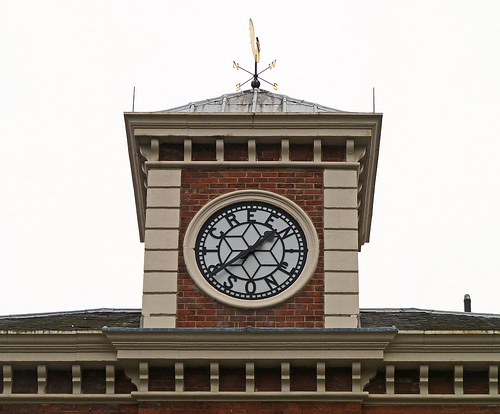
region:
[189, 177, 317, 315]
clock on top of tower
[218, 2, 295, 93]
weather vane on tower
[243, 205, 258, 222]
letter on clock face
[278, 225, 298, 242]
letter on clock face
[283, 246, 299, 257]
letter on clock face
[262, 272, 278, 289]
letter on clock face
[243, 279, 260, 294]
letter on clock face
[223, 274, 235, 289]
letter on clock face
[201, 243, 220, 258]
letter on clock face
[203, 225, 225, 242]
letter on clock face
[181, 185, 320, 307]
a clock on the front of a church.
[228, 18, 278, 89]
a metal weather vane.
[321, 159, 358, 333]
stack of bricks on a building.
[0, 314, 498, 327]
a roof on top of a building.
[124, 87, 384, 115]
pyramid on top of a clock tower.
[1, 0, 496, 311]
a hazy gray sky.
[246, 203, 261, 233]
the letter e on a clock.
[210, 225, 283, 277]
two black clock hands.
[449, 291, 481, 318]
an exhaust vent on a roof.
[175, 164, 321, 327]
brown bricks behind a clock.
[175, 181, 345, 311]
white and black clock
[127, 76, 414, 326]
clock on top of building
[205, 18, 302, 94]
gold and black weather vane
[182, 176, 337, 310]
clock with letters to represent numbers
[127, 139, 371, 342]
red brick building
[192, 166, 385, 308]
clock with black hands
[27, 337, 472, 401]
white decorative accent around roof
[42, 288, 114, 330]
black shingled roof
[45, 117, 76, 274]
clear white sky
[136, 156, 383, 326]
white shingles on either side of clock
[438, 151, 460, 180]
part of a cloud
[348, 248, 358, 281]
edge of a wall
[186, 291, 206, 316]
part of a brick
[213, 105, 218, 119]
edge of a roof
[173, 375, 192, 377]
bottom of a roof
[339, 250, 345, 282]
white part of a wall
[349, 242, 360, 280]
edge of a clock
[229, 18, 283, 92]
a weather vain on top of a roof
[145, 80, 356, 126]
a metal roof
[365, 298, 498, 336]
a shingled roof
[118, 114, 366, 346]
a brick cupola on top of a building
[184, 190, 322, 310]
a clock on the side of a cupola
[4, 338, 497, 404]
a decorative railing below the eaves of a roof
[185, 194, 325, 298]
letters on a clock face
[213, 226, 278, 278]
two black clock hands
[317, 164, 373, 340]
concrete stone at the corner of a cupola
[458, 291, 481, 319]
a vent in a roof